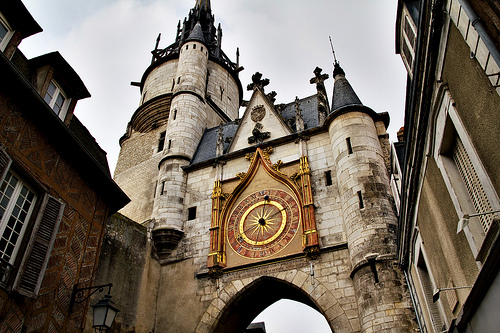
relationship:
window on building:
[0, 142, 70, 302] [1, 1, 138, 332]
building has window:
[1, 1, 138, 332] [0, 142, 70, 302]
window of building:
[0, 142, 70, 302] [1, 1, 138, 332]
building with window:
[1, 1, 138, 332] [0, 142, 70, 302]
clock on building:
[212, 148, 311, 269] [1, 1, 138, 332]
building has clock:
[1, 1, 138, 332] [212, 148, 311, 269]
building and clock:
[1, 1, 138, 332] [212, 148, 311, 269]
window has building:
[0, 142, 70, 302] [1, 1, 138, 332]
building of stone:
[1, 1, 138, 332] [165, 123, 192, 135]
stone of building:
[165, 123, 192, 135] [1, 1, 138, 332]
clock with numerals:
[212, 148, 311, 269] [257, 188, 290, 209]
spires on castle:
[316, 31, 367, 121] [116, 1, 417, 332]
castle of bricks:
[116, 1, 417, 332] [334, 166, 380, 229]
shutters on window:
[37, 189, 69, 271] [0, 142, 70, 302]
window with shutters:
[0, 142, 70, 302] [37, 189, 69, 271]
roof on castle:
[200, 124, 237, 144] [116, 1, 417, 332]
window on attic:
[0, 142, 70, 302] [24, 46, 96, 145]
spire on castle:
[316, 31, 367, 121] [116, 1, 417, 332]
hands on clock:
[256, 193, 287, 230] [212, 148, 311, 269]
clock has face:
[212, 148, 311, 269] [227, 191, 301, 265]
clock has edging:
[212, 148, 311, 269] [294, 159, 332, 270]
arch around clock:
[237, 144, 282, 185] [212, 148, 311, 269]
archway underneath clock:
[192, 264, 350, 331] [212, 148, 311, 269]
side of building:
[62, 219, 97, 326] [1, 1, 138, 332]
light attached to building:
[76, 276, 134, 332] [1, 1, 138, 332]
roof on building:
[200, 124, 237, 144] [1, 1, 138, 332]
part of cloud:
[83, 17, 97, 36] [72, 8, 136, 59]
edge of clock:
[202, 252, 221, 273] [212, 148, 311, 269]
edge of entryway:
[202, 252, 221, 273] [210, 274, 336, 333]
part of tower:
[83, 17, 97, 36] [172, 15, 212, 164]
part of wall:
[83, 17, 97, 36] [78, 193, 92, 250]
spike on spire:
[325, 28, 340, 70] [316, 31, 367, 121]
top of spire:
[333, 57, 349, 81] [326, 55, 370, 126]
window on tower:
[0, 142, 70, 302] [172, 15, 212, 164]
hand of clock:
[269, 201, 292, 224] [212, 148, 311, 269]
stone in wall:
[165, 123, 192, 135] [78, 193, 92, 250]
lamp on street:
[76, 276, 134, 332] [88, 175, 209, 330]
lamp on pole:
[76, 276, 134, 332] [63, 296, 77, 317]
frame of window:
[4, 169, 39, 211] [0, 142, 70, 302]